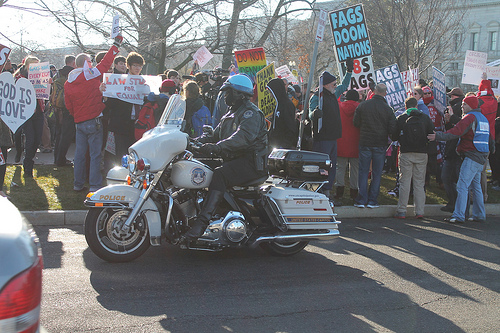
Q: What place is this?
A: It is a street.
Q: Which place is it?
A: It is a street.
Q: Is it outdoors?
A: Yes, it is outdoors.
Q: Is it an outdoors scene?
A: Yes, it is outdoors.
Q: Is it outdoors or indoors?
A: It is outdoors.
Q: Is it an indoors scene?
A: No, it is outdoors.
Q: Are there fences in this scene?
A: No, there are no fences.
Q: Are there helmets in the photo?
A: Yes, there is a helmet.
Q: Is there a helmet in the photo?
A: Yes, there is a helmet.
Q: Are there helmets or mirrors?
A: Yes, there is a helmet.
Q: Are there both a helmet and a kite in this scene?
A: No, there is a helmet but no kites.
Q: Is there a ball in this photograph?
A: No, there are no balls.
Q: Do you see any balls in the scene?
A: No, there are no balls.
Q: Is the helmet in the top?
A: Yes, the helmet is in the top of the image.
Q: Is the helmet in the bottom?
A: No, the helmet is in the top of the image.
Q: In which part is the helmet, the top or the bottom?
A: The helmet is in the top of the image.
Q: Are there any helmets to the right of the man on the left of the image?
A: Yes, there is a helmet to the right of the man.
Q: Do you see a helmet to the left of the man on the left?
A: No, the helmet is to the right of the man.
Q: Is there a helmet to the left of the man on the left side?
A: No, the helmet is to the right of the man.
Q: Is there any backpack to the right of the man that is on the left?
A: No, there is a helmet to the right of the man.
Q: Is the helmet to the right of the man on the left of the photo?
A: Yes, the helmet is to the right of the man.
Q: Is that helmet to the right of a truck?
A: No, the helmet is to the right of the man.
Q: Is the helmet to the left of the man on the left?
A: No, the helmet is to the right of the man.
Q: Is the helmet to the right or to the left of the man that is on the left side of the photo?
A: The helmet is to the right of the man.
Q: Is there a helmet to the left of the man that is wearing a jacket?
A: Yes, there is a helmet to the left of the man.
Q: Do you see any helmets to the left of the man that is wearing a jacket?
A: Yes, there is a helmet to the left of the man.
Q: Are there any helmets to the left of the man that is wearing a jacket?
A: Yes, there is a helmet to the left of the man.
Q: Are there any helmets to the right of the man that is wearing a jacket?
A: No, the helmet is to the left of the man.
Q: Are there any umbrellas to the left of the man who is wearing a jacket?
A: No, there is a helmet to the left of the man.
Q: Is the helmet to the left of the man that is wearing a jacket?
A: Yes, the helmet is to the left of the man.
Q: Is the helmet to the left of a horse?
A: No, the helmet is to the left of the man.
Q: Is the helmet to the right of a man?
A: No, the helmet is to the left of a man.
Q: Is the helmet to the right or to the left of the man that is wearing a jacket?
A: The helmet is to the left of the man.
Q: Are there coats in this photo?
A: Yes, there is a coat.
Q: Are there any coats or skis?
A: Yes, there is a coat.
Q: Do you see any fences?
A: No, there are no fences.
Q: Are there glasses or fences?
A: No, there are no fences or glasses.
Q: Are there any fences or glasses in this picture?
A: No, there are no fences or glasses.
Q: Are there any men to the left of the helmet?
A: Yes, there is a man to the left of the helmet.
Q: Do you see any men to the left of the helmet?
A: Yes, there is a man to the left of the helmet.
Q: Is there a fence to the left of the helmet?
A: No, there is a man to the left of the helmet.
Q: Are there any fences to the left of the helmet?
A: No, there is a man to the left of the helmet.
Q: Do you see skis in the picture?
A: No, there are no skis.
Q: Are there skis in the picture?
A: No, there are no skis.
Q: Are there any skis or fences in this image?
A: No, there are no skis or fences.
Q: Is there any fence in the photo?
A: No, there are no fences.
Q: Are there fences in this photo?
A: No, there are no fences.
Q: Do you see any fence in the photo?
A: No, there are no fences.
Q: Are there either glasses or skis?
A: No, there are no glasses or skis.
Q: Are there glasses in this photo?
A: No, there are no glasses.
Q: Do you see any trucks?
A: No, there are no trucks.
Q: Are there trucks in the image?
A: No, there are no trucks.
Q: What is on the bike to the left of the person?
A: The container is on the bike.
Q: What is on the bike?
A: The container is on the bike.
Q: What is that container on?
A: The container is on the bike.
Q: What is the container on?
A: The container is on the bike.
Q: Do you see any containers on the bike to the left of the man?
A: Yes, there is a container on the bike.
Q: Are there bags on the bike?
A: No, there is a container on the bike.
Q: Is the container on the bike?
A: Yes, the container is on the bike.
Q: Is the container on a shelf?
A: No, the container is on the bike.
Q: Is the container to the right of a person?
A: No, the container is to the left of a person.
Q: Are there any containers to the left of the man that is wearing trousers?
A: Yes, there is a container to the left of the man.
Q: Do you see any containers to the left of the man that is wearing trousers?
A: Yes, there is a container to the left of the man.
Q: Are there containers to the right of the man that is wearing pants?
A: No, the container is to the left of the man.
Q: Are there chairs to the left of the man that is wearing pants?
A: No, there is a container to the left of the man.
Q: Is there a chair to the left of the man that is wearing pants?
A: No, there is a container to the left of the man.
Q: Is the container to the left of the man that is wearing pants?
A: Yes, the container is to the left of the man.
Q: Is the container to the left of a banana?
A: No, the container is to the left of the man.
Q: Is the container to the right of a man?
A: No, the container is to the left of a man.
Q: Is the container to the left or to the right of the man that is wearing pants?
A: The container is to the left of the man.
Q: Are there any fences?
A: No, there are no fences.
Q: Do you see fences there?
A: No, there are no fences.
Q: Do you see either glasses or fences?
A: No, there are no fences or glasses.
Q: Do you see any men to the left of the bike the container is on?
A: No, the man is to the right of the bike.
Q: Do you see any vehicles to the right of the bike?
A: No, there is a man to the right of the bike.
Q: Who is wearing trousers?
A: The man is wearing trousers.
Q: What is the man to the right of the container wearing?
A: The man is wearing pants.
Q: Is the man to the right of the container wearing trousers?
A: Yes, the man is wearing trousers.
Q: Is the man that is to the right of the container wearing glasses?
A: No, the man is wearing trousers.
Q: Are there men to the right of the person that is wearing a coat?
A: Yes, there is a man to the right of the person.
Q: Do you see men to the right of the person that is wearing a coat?
A: Yes, there is a man to the right of the person.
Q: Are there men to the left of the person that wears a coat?
A: No, the man is to the right of the person.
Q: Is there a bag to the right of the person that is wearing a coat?
A: No, there is a man to the right of the person.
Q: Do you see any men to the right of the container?
A: Yes, there is a man to the right of the container.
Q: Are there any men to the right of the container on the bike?
A: Yes, there is a man to the right of the container.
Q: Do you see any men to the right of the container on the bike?
A: Yes, there is a man to the right of the container.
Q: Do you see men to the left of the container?
A: No, the man is to the right of the container.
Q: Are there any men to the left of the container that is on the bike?
A: No, the man is to the right of the container.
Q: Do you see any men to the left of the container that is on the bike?
A: No, the man is to the right of the container.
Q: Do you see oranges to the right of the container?
A: No, there is a man to the right of the container.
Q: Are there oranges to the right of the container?
A: No, there is a man to the right of the container.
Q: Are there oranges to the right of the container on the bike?
A: No, there is a man to the right of the container.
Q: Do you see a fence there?
A: No, there are no fences.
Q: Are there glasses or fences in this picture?
A: No, there are no fences or glasses.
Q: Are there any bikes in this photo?
A: Yes, there is a bike.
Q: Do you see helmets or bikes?
A: Yes, there is a bike.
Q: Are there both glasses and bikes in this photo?
A: No, there is a bike but no glasses.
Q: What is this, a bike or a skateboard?
A: This is a bike.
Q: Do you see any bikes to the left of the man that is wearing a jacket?
A: Yes, there is a bike to the left of the man.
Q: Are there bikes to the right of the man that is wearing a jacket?
A: No, the bike is to the left of the man.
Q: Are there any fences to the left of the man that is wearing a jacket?
A: No, there is a bike to the left of the man.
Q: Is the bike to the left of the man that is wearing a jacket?
A: Yes, the bike is to the left of the man.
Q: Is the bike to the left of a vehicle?
A: No, the bike is to the left of the man.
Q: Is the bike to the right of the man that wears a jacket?
A: No, the bike is to the left of the man.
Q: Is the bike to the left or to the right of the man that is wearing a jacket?
A: The bike is to the left of the man.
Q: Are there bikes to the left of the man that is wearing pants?
A: Yes, there is a bike to the left of the man.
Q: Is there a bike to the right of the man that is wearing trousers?
A: No, the bike is to the left of the man.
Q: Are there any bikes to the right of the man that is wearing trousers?
A: No, the bike is to the left of the man.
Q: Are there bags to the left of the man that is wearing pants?
A: No, there is a bike to the left of the man.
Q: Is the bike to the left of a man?
A: Yes, the bike is to the left of a man.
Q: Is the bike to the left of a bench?
A: No, the bike is to the left of a man.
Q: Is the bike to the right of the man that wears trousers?
A: No, the bike is to the left of the man.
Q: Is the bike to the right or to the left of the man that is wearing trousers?
A: The bike is to the left of the man.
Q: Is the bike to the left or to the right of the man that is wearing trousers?
A: The bike is to the left of the man.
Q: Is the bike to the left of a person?
A: Yes, the bike is to the left of a person.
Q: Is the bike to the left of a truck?
A: No, the bike is to the left of a person.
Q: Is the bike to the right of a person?
A: No, the bike is to the left of a person.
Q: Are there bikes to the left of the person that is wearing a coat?
A: Yes, there is a bike to the left of the person.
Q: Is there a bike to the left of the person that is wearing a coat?
A: Yes, there is a bike to the left of the person.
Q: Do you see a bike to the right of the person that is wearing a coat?
A: No, the bike is to the left of the person.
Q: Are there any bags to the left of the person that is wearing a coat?
A: No, there is a bike to the left of the person.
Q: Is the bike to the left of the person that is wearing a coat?
A: Yes, the bike is to the left of the person.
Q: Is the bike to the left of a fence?
A: No, the bike is to the left of the person.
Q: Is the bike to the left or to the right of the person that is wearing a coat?
A: The bike is to the left of the person.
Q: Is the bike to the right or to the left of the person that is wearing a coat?
A: The bike is to the left of the person.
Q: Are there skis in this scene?
A: No, there are no skis.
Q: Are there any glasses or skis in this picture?
A: No, there are no skis or glasses.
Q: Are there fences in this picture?
A: No, there are no fences.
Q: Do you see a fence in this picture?
A: No, there are no fences.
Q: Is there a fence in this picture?
A: No, there are no fences.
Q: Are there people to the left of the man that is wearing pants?
A: Yes, there is a person to the left of the man.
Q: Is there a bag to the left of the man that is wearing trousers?
A: No, there is a person to the left of the man.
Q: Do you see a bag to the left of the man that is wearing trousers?
A: No, there is a person to the left of the man.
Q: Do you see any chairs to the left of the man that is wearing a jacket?
A: No, there is a person to the left of the man.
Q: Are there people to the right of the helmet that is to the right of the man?
A: Yes, there is a person to the right of the helmet.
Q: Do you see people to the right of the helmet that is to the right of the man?
A: Yes, there is a person to the right of the helmet.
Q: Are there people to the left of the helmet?
A: No, the person is to the right of the helmet.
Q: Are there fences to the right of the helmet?
A: No, there is a person to the right of the helmet.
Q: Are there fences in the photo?
A: No, there are no fences.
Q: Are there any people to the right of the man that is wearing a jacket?
A: Yes, there is a person to the right of the man.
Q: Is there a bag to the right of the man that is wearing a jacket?
A: No, there is a person to the right of the man.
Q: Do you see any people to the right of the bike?
A: Yes, there is a person to the right of the bike.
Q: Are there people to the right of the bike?
A: Yes, there is a person to the right of the bike.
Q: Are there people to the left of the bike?
A: No, the person is to the right of the bike.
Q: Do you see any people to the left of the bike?
A: No, the person is to the right of the bike.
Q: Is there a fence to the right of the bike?
A: No, there is a person to the right of the bike.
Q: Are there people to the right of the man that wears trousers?
A: Yes, there is a person to the right of the man.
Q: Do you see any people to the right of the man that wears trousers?
A: Yes, there is a person to the right of the man.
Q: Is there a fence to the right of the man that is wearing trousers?
A: No, there is a person to the right of the man.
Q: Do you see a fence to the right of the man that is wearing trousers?
A: No, there is a person to the right of the man.